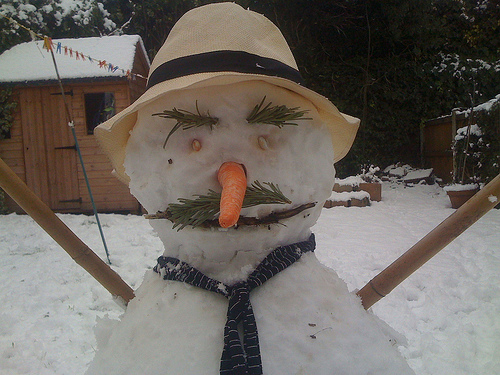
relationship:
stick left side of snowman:
[2, 157, 157, 317] [89, 45, 379, 363]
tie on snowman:
[156, 252, 323, 367] [75, 44, 412, 372]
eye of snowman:
[185, 135, 203, 154] [116, 107, 324, 360]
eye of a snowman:
[257, 126, 278, 158] [105, 11, 407, 373]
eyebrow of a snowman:
[246, 93, 315, 130] [105, 11, 407, 373]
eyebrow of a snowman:
[151, 98, 220, 150] [105, 11, 407, 373]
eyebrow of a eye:
[151, 98, 220, 150] [257, 134, 273, 152]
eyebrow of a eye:
[246, 93, 315, 130] [189, 138, 203, 153]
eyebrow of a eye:
[151, 98, 220, 150] [189, 138, 203, 153]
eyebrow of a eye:
[246, 93, 315, 130] [257, 134, 273, 152]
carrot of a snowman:
[217, 161, 249, 229] [80, 0, 430, 373]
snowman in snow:
[116, 102, 353, 350] [311, 311, 375, 371]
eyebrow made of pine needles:
[246, 93, 315, 130] [145, 96, 330, 142]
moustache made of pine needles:
[150, 183, 292, 226] [163, 203, 218, 215]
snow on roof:
[19, 43, 105, 67] [4, 31, 153, 85]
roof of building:
[4, 31, 153, 85] [1, 39, 161, 224]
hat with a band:
[92, 0, 362, 188] [160, 55, 288, 74]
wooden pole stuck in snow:
[367, 183, 478, 293] [344, 223, 457, 306]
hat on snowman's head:
[143, 0, 320, 110] [116, 93, 346, 248]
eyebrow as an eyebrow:
[246, 93, 315, 130] [147, 100, 221, 140]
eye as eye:
[189, 138, 203, 153] [188, 136, 203, 152]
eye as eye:
[257, 134, 273, 152] [188, 136, 203, 152]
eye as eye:
[257, 134, 273, 152] [256, 132, 271, 152]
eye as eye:
[189, 138, 203, 153] [256, 132, 271, 152]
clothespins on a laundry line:
[47, 33, 117, 79] [10, 10, 151, 85]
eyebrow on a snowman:
[242, 94, 314, 129] [65, 3, 403, 373]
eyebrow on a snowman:
[153, 100, 225, 141] [65, 3, 403, 373]